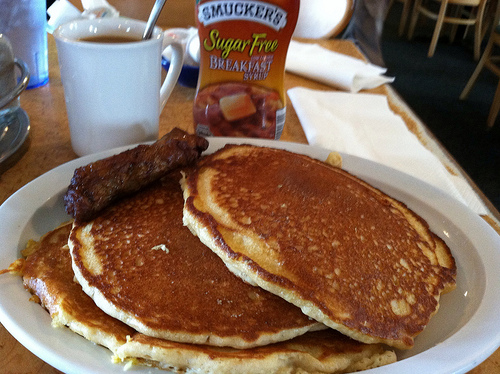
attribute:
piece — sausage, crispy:
[59, 126, 211, 225]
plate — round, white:
[3, 136, 498, 373]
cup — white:
[51, 16, 186, 157]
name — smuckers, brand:
[197, 3, 289, 33]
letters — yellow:
[202, 27, 281, 60]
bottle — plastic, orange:
[190, 2, 302, 140]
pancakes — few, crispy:
[2, 143, 459, 373]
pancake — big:
[181, 142, 459, 353]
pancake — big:
[68, 155, 329, 350]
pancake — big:
[7, 220, 399, 372]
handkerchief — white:
[284, 85, 489, 219]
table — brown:
[0, 4, 497, 373]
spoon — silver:
[139, 2, 167, 42]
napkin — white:
[284, 40, 398, 94]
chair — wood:
[458, 4, 498, 128]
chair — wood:
[406, 1, 491, 63]